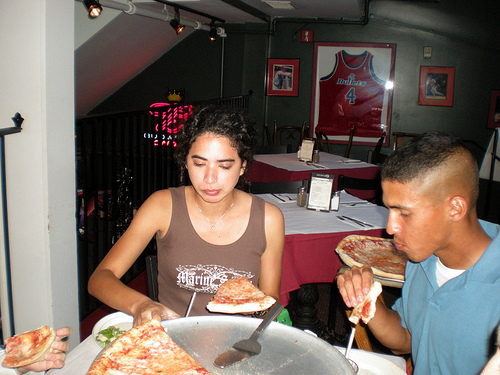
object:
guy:
[334, 128, 499, 373]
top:
[74, 0, 466, 21]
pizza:
[86, 317, 216, 375]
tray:
[162, 313, 359, 374]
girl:
[85, 101, 285, 327]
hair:
[172, 102, 262, 194]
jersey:
[313, 49, 386, 138]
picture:
[415, 64, 455, 107]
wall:
[74, 19, 500, 156]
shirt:
[389, 217, 500, 375]